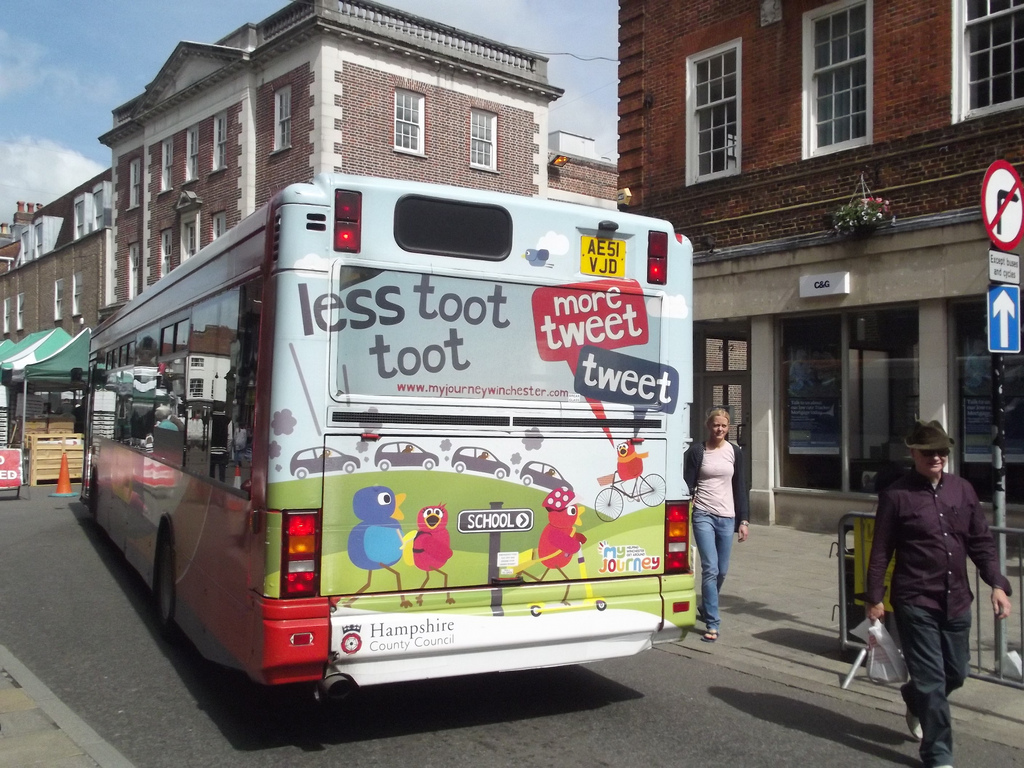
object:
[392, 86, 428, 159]
window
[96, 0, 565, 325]
building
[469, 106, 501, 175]
window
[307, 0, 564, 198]
building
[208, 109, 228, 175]
building window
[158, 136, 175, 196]
building window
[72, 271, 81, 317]
building window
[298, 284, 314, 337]
letter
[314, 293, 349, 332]
letter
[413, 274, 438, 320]
letter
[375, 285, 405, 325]
letter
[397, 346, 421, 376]
letter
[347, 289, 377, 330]
letter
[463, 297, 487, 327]
letter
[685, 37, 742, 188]
building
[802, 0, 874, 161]
building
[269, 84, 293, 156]
building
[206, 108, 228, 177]
building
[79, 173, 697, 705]
bus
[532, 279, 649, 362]
sign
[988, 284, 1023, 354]
sign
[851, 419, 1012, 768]
man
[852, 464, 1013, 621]
shirt